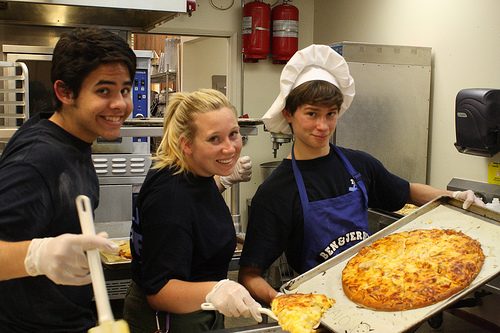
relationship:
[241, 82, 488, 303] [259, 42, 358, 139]
boy wearing hat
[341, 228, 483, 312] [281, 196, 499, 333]
pizza on tray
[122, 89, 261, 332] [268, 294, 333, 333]
girl holding pizza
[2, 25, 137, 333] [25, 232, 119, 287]
boy wearing glove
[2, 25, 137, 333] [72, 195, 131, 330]
boy holding spoon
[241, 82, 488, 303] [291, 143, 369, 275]
boy wearing apron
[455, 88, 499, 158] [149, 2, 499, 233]
dispenser on wall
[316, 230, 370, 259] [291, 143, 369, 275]
logo on apron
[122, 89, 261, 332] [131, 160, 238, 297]
girl wearing shirt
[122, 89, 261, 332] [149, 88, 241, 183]
girl has hair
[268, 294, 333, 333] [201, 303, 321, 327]
pizza on spatula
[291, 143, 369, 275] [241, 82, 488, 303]
apron on boy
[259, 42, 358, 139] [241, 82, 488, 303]
hat on boy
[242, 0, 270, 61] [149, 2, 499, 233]
fire extinguisher on wall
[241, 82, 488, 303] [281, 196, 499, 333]
boy holding tray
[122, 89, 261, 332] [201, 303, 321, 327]
girl holding spatula